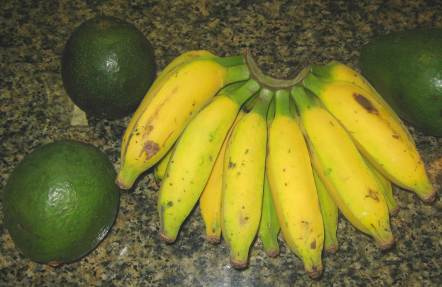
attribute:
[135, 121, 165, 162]
spot — large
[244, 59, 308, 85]
core — brown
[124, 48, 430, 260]
fruit — yellow 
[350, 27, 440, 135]
fruit — green 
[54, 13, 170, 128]
fruit — green 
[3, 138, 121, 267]
fruit — green 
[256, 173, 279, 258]
banana — green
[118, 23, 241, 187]
banana — curved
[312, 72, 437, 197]
banana — yellow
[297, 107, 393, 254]
banana — yellow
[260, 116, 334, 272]
banana — yellow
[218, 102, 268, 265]
banana — yellow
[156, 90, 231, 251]
banana — yellow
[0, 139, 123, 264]
avocado — green 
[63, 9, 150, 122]
avocado — green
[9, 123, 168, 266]
avocado — green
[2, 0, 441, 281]
fruit — lime, bananas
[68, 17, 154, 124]
fruit — yellow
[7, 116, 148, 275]
fruit — round, green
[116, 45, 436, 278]
fruit — tropical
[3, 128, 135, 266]
avocado — round 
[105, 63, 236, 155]
banana — yellow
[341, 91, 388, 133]
bruise — brown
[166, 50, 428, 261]
bananas — ripe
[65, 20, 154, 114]
fruits — green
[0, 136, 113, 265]
fruits — green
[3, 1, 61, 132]
counter top — granite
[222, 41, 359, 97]
stem — green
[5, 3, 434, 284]
counter — marble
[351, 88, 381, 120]
spot — dark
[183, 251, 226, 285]
reflection — light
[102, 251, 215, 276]
countertop — granite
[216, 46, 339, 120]
stalk — green 